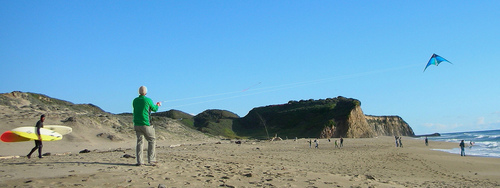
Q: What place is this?
A: It is a shore.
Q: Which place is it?
A: It is a shore.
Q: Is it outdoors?
A: Yes, it is outdoors.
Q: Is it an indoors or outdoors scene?
A: It is outdoors.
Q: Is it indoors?
A: No, it is outdoors.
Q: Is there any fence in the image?
A: No, there are no fences.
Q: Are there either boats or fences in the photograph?
A: No, there are no fences or boats.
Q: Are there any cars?
A: No, there are no cars.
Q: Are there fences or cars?
A: No, there are no cars or fences.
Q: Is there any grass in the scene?
A: Yes, there is grass.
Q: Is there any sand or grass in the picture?
A: Yes, there is grass.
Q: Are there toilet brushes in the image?
A: No, there are no toilet brushes.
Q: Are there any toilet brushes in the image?
A: No, there are no toilet brushes.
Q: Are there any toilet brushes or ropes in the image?
A: No, there are no toilet brushes or ropes.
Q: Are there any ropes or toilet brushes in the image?
A: No, there are no toilet brushes or ropes.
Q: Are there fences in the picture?
A: No, there are no fences.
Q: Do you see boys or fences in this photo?
A: No, there are no fences or boys.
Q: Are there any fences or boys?
A: No, there are no fences or boys.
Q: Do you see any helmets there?
A: No, there are no helmets.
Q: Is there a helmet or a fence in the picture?
A: No, there are no helmets or fences.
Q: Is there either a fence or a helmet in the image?
A: No, there are no helmets or fences.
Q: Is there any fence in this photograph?
A: No, there are no fences.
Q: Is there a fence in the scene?
A: No, there are no fences.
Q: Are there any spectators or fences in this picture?
A: No, there are no fences or spectators.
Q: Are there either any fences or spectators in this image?
A: No, there are no fences or spectators.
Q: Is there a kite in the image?
A: Yes, there is a kite.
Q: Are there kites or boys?
A: Yes, there is a kite.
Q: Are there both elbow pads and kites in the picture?
A: No, there is a kite but no elbow pads.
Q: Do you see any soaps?
A: No, there are no soaps.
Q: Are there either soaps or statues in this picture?
A: No, there are no soaps or statues.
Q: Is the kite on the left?
A: No, the kite is on the right of the image.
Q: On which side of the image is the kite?
A: The kite is on the right of the image.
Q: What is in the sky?
A: The kite is in the sky.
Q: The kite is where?
A: The kite is in the sky.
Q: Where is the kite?
A: The kite is in the sky.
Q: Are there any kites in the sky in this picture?
A: Yes, there is a kite in the sky.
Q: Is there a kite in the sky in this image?
A: Yes, there is a kite in the sky.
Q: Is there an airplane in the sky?
A: No, there is a kite in the sky.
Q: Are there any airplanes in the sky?
A: No, there is a kite in the sky.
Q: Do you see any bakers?
A: No, there are no bakers.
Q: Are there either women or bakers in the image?
A: No, there are no bakers or women.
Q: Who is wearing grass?
A: The man is wearing grass.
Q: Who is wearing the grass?
A: The man is wearing grass.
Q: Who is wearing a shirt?
A: The man is wearing a shirt.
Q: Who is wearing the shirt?
A: The man is wearing a shirt.